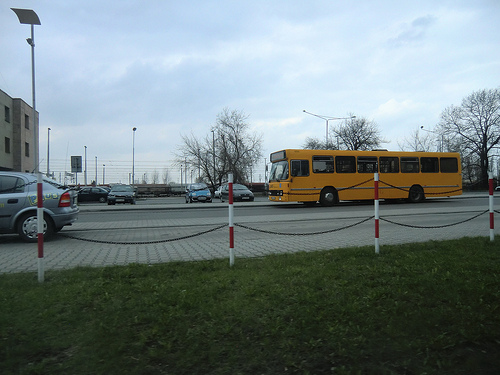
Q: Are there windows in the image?
A: Yes, there are windows.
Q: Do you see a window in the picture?
A: Yes, there are windows.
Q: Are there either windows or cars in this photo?
A: Yes, there are windows.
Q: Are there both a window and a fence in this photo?
A: Yes, there are both a window and a fence.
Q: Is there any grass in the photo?
A: Yes, there is grass.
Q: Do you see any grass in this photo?
A: Yes, there is grass.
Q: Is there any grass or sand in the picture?
A: Yes, there is grass.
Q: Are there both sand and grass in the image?
A: No, there is grass but no sand.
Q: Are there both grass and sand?
A: No, there is grass but no sand.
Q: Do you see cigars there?
A: No, there are no cigars.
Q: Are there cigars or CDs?
A: No, there are no cigars or cds.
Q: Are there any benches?
A: No, there are no benches.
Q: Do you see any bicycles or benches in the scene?
A: No, there are no benches or bicycles.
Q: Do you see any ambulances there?
A: No, there are no ambulances.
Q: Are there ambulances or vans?
A: No, there are no ambulances or vans.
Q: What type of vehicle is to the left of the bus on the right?
A: The vehicle is a car.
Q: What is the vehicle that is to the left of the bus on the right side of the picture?
A: The vehicle is a car.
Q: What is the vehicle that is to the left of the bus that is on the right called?
A: The vehicle is a car.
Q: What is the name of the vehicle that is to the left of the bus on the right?
A: The vehicle is a car.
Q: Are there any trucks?
A: No, there are no trucks.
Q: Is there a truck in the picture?
A: No, there are no trucks.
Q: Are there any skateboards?
A: No, there are no skateboards.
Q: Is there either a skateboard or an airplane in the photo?
A: No, there are no skateboards or airplanes.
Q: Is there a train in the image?
A: No, there are no trains.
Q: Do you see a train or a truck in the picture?
A: No, there are no trains or trucks.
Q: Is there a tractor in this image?
A: No, there are no tractors.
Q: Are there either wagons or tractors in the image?
A: No, there are no tractors or wagons.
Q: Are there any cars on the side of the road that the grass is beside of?
A: Yes, there is a car on the side of the road.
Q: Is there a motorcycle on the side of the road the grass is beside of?
A: No, there is a car on the side of the road.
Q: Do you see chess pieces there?
A: No, there are no chess pieces.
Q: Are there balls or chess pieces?
A: No, there are no chess pieces or balls.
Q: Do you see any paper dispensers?
A: No, there are no paper dispensers.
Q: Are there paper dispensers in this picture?
A: No, there are no paper dispensers.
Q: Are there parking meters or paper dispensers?
A: No, there are no paper dispensers or parking meters.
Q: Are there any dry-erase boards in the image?
A: No, there are no dry-erase boards.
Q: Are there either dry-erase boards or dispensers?
A: No, there are no dry-erase boards or dispensers.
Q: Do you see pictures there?
A: No, there are no pictures.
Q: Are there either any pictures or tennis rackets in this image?
A: No, there are no pictures or tennis rackets.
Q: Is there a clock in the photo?
A: No, there are no clocks.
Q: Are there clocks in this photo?
A: No, there are no clocks.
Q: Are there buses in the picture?
A: Yes, there is a bus.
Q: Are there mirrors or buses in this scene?
A: Yes, there is a bus.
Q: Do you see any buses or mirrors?
A: Yes, there is a bus.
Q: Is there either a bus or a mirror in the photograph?
A: Yes, there is a bus.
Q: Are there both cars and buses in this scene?
A: Yes, there are both a bus and a car.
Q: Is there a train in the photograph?
A: No, there are no trains.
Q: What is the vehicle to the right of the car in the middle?
A: The vehicle is a bus.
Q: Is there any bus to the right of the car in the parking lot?
A: Yes, there is a bus to the right of the car.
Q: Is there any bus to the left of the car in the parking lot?
A: No, the bus is to the right of the car.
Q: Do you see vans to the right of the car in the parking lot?
A: No, there is a bus to the right of the car.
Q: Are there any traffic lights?
A: No, there are no traffic lights.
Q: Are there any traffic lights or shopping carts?
A: No, there are no traffic lights or shopping carts.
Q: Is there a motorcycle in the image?
A: No, there are no motorcycles.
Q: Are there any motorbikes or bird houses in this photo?
A: No, there are no motorbikes or bird houses.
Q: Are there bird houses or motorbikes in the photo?
A: No, there are no motorbikes or bird houses.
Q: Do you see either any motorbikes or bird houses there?
A: No, there are no motorbikes or bird houses.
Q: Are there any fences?
A: Yes, there is a fence.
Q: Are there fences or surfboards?
A: Yes, there is a fence.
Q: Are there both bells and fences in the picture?
A: No, there is a fence but no bells.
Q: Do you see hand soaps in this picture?
A: No, there are no hand soaps.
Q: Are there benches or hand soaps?
A: No, there are no hand soaps or benches.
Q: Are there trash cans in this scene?
A: No, there are no trash cans.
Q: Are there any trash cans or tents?
A: No, there are no trash cans or tents.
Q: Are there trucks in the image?
A: No, there are no trucks.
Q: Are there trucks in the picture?
A: No, there are no trucks.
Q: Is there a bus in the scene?
A: Yes, there is a bus.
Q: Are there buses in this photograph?
A: Yes, there is a bus.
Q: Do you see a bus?
A: Yes, there is a bus.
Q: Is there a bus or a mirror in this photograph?
A: Yes, there is a bus.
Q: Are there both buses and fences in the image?
A: Yes, there are both a bus and a fence.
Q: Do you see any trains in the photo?
A: No, there are no trains.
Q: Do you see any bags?
A: No, there are no bags.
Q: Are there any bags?
A: No, there are no bags.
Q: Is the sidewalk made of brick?
A: Yes, the sidewalk is made of brick.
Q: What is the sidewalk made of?
A: The sidewalk is made of brick.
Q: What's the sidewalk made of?
A: The sidewalk is made of brick.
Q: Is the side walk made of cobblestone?
A: No, the side walk is made of brick.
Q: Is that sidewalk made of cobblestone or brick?
A: The sidewalk is made of brick.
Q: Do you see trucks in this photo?
A: No, there are no trucks.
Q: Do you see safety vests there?
A: No, there are no safety vests.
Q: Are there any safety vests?
A: No, there are no safety vests.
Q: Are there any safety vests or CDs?
A: No, there are no safety vests or cds.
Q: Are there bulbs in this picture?
A: No, there are no bulbs.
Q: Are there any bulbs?
A: No, there are no bulbs.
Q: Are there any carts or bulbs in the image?
A: No, there are no bulbs or carts.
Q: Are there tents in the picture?
A: No, there are no tents.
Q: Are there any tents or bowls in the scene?
A: No, there are no tents or bowls.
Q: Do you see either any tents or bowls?
A: No, there are no tents or bowls.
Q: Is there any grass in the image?
A: Yes, there is grass.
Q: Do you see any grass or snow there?
A: Yes, there is grass.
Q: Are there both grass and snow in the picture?
A: No, there is grass but no snow.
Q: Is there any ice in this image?
A: No, there is no ice.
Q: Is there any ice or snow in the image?
A: No, there are no ice or snow.